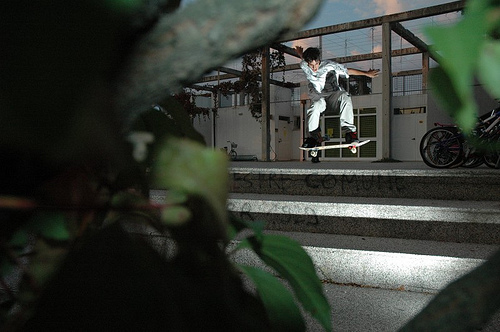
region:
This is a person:
[271, 26, 386, 171]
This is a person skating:
[283, 37, 386, 165]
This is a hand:
[325, 56, 387, 84]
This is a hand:
[284, 42, 305, 78]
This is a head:
[301, 46, 325, 73]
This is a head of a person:
[301, 46, 323, 74]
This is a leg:
[336, 88, 362, 147]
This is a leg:
[301, 96, 336, 154]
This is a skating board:
[292, 133, 374, 161]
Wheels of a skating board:
[301, 147, 371, 160]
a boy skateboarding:
[279, 32, 404, 187]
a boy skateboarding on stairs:
[258, 16, 430, 203]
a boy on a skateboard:
[234, 2, 441, 190]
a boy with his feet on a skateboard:
[265, 13, 360, 162]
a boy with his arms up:
[251, 7, 430, 227]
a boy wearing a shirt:
[255, 17, 432, 215]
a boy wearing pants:
[266, 12, 421, 191]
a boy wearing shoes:
[265, 30, 385, 185]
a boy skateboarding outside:
[252, 28, 372, 149]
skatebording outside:
[259, 2, 385, 177]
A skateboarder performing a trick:
[22, 12, 491, 314]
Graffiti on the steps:
[207, 161, 427, 210]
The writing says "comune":
[298, 164, 425, 203]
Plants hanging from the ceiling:
[217, 68, 270, 119]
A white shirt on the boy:
[307, 65, 354, 100]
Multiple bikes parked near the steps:
[422, 117, 490, 171]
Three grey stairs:
[177, 165, 460, 280]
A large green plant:
[27, 4, 314, 311]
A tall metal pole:
[363, 11, 395, 158]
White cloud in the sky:
[374, 0, 426, 45]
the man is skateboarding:
[280, 22, 395, 154]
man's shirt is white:
[297, 59, 364, 119]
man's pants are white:
[293, 89, 395, 157]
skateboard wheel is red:
[343, 135, 360, 157]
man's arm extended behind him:
[285, 37, 312, 77]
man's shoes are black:
[293, 114, 380, 155]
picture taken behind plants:
[2, 0, 474, 329]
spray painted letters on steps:
[227, 163, 412, 228]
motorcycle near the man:
[418, 101, 498, 163]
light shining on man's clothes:
[295, 61, 373, 147]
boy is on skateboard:
[283, 46, 412, 158]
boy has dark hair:
[294, 30, 342, 88]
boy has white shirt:
[295, 46, 360, 105]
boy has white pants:
[306, 86, 381, 161]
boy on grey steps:
[249, 162, 394, 254]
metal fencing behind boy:
[250, 3, 417, 53]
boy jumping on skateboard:
[295, 49, 367, 151]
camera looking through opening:
[207, 33, 419, 292]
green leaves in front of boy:
[200, 217, 348, 314]